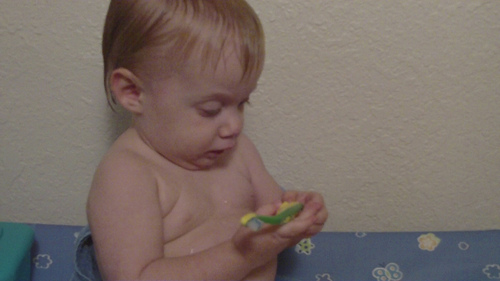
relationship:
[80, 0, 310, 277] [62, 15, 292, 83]
baby with hair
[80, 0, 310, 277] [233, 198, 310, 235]
baby inspecting toothbrush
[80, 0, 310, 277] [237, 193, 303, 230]
baby holding toothbrush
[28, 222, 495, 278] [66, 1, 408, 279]
bumper around baby